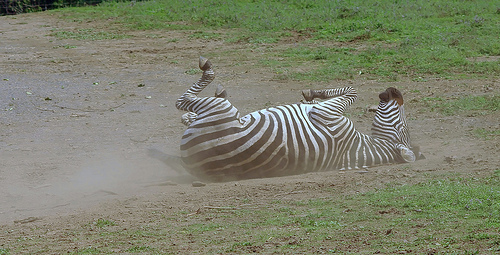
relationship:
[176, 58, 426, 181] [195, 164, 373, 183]
zebra laying on its back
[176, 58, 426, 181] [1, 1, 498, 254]
zebra rolling in dirt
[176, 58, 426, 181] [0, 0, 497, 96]
zebra looking up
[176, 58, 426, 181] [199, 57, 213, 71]
zebra with hoof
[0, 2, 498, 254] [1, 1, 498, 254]
land with dirt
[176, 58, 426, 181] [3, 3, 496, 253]
zebra enjoying light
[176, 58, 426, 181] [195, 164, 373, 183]
zebra on back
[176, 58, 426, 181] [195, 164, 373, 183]
zebra on its back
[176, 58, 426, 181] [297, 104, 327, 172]
zebra has stripe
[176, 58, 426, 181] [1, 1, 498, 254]
zebra rolls in dirt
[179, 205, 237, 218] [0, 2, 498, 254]
stick on ground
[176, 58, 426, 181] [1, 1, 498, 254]
zebra in dirt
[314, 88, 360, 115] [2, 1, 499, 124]
leg in air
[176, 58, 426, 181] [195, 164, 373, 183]
zebra scratching back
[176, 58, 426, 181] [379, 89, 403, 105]
zebra has nose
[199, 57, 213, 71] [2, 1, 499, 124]
hoof in air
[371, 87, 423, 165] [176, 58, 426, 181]
head of zebra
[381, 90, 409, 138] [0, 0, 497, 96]
face pointing up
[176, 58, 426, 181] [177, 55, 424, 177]
zebra has side view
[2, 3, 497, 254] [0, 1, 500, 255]
photo taken in air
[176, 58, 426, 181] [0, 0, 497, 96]
zebra pointing up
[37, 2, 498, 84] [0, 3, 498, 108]
grass in background